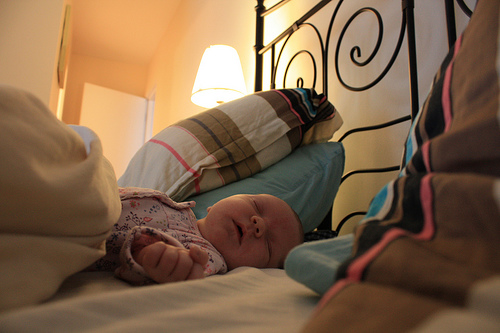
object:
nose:
[250, 215, 270, 238]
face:
[206, 191, 306, 271]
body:
[77, 186, 228, 287]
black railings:
[253, 0, 479, 240]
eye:
[248, 196, 264, 216]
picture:
[56, 4, 74, 90]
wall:
[0, 0, 73, 108]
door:
[78, 82, 148, 183]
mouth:
[231, 218, 248, 247]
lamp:
[190, 43, 249, 109]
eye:
[265, 238, 277, 263]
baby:
[79, 186, 307, 285]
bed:
[0, 80, 500, 333]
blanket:
[0, 77, 123, 315]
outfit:
[82, 185, 228, 286]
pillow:
[116, 88, 344, 203]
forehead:
[261, 193, 301, 268]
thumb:
[188, 244, 209, 265]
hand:
[138, 241, 209, 285]